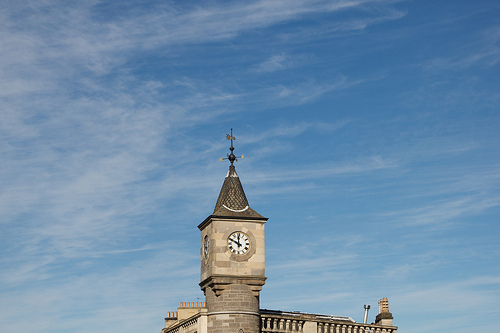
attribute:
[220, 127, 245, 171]
cross — a weathervane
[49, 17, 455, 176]
sky — blue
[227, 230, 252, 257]
clock face — round, white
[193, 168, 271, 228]
roof — black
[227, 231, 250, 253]
clock — white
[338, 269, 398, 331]
object — silver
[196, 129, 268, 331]
tower — stone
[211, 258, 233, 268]
bricks — stone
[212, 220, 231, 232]
bricks — stone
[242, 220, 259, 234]
bricks — stone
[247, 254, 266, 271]
bricks — stone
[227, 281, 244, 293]
bricks — stone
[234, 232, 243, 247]
hand — black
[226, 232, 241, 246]
hand — black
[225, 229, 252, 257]
clock — white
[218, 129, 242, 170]
weather vane — metal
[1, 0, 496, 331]
sky — blue, clear, cloudless, bright, sunny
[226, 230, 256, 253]
time — 11:50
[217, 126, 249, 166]
weather vane — black, metal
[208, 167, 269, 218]
pointed roof — brown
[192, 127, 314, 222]
vane — on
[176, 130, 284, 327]
tower — has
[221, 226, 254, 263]
clock — white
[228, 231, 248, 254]
clock — round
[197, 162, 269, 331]
tower — peaked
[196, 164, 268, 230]
roof — black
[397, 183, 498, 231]
cloud — wispy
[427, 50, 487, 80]
cloud — wispy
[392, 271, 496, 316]
cloud — wispy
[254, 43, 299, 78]
cloud — wispy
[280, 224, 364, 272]
cloud — wispy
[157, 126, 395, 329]
church — old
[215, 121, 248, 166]
vane — weather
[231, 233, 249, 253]
numerals — roman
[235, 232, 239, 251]
hand — black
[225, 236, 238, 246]
hand — black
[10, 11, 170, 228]
clouds — thin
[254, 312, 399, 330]
rail — brown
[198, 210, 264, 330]
tower — stone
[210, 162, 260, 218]
roof — black